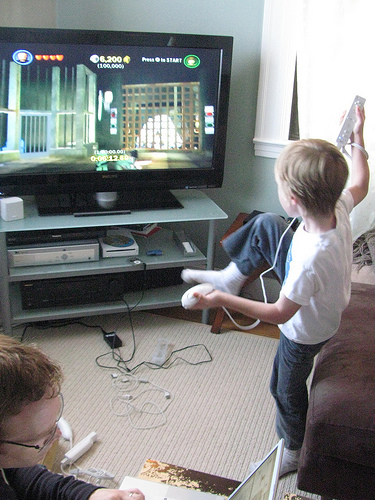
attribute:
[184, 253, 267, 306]
socks — white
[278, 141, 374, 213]
hair — blonde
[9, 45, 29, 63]
character — small, lego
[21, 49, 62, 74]
hearts — red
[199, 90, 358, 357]
boy — little, playing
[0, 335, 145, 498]
boy — little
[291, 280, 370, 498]
sofa — brown, cushioned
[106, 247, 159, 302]
ipod — plugged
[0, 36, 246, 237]
tv — flat screen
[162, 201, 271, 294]
leg — lifted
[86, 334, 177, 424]
cord — laying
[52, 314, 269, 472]
rug — beige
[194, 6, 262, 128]
walls — grey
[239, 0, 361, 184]
window — white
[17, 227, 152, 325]
equipment — audio visual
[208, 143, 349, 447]
kid — playing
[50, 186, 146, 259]
bar — black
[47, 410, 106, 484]
controller — white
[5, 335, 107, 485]
man — looking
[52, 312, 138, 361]
cord — black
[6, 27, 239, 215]
tv — large, flat screen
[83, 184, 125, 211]
speaker — small, square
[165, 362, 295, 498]
rug — beige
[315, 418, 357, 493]
sofa — dark brown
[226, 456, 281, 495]
screen — computer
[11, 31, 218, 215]
tv set — large, black, flatscreen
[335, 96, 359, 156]
controller — white, game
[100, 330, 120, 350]
power supply — black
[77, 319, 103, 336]
cord — black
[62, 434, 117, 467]
controller — video game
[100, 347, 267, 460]
rug — white, area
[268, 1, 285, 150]
casement — window, white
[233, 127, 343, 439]
child — blond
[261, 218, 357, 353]
t-shirt — white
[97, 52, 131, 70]
score — game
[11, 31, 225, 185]
screen — TV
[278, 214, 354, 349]
tee shirt — white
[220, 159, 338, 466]
boy — young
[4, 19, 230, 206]
television — large, black, flat screen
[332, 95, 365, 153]
control — wii, game console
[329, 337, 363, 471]
cushion — brown, couch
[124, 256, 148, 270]
ipod — small, silver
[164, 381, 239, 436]
carpet — striped, taupe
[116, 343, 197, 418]
cords — electrical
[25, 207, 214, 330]
entertainment center — silver, metal, glass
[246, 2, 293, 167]
window — white, wood, framed, painted